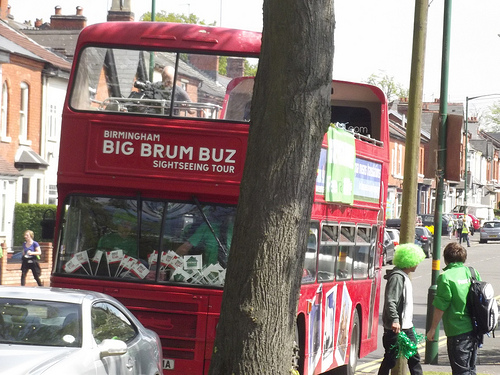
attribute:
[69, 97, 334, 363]
bus — red, side, top, parked, tour, double decker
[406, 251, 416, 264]
wig — green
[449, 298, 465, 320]
shirt — green, purple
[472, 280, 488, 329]
backpack — grey, black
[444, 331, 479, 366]
pants — worn, pair, black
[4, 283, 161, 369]
car — silver, the car, parked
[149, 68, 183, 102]
man — sitting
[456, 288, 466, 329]
jacket — green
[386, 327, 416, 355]
pom poms — green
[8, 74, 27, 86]
wall — red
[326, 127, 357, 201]
banner — green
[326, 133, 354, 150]
sign — green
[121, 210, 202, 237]
windshield — bottom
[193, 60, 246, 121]
window — side